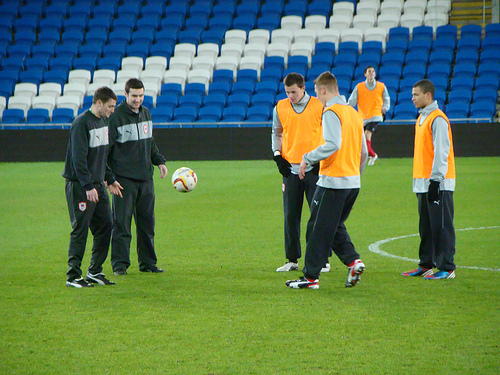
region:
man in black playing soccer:
[57, 82, 119, 292]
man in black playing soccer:
[113, 72, 171, 275]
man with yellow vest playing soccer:
[401, 76, 462, 293]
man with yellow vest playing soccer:
[308, 66, 365, 304]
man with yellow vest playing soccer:
[265, 67, 312, 275]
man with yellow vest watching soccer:
[355, 53, 384, 167]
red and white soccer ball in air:
[163, 160, 203, 196]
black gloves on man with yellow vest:
[269, 146, 294, 177]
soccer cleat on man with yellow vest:
[339, 256, 366, 287]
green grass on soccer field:
[31, 302, 446, 362]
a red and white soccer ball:
[167, 166, 202, 192]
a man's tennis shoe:
[287, 271, 319, 290]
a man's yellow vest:
[322, 103, 362, 173]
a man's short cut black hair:
[409, 80, 438, 101]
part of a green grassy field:
[124, 296, 497, 373]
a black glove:
[271, 157, 298, 179]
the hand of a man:
[160, 161, 172, 179]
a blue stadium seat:
[210, 80, 232, 91]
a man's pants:
[101, 178, 158, 266]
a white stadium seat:
[169, 55, 191, 69]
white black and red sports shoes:
[284, 274, 323, 294]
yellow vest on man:
[317, 99, 366, 181]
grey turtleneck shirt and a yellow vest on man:
[302, 92, 376, 194]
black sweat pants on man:
[296, 180, 367, 282]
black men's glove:
[269, 152, 294, 179]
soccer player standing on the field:
[399, 78, 465, 287]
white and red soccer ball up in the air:
[167, 163, 201, 198]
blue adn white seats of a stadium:
[1, 0, 498, 132]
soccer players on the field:
[259, 70, 466, 298]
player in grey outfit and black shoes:
[57, 83, 124, 297]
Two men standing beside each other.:
[64, 78, 165, 288]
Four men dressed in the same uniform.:
[271, 63, 459, 288]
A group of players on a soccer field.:
[63, 63, 471, 290]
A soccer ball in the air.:
[170, 163, 198, 195]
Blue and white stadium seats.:
[1, 0, 498, 118]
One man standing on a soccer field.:
[403, 78, 465, 285]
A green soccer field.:
[0, 163, 496, 372]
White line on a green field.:
[366, 225, 498, 276]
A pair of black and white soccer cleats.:
[61, 271, 118, 290]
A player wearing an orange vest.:
[407, 80, 462, 282]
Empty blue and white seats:
[1, 0, 496, 127]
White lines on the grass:
[365, 215, 495, 275]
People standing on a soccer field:
[0, 65, 495, 370]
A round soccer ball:
[165, 160, 200, 196]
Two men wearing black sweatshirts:
[57, 71, 167, 187]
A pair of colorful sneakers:
[398, 258, 460, 283]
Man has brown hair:
[275, 65, 311, 107]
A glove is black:
[420, 175, 445, 210]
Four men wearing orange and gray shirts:
[262, 60, 467, 195]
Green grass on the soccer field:
[0, 155, 496, 373]